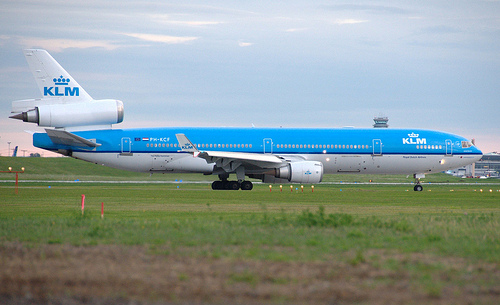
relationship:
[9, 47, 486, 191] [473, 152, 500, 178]
plane at airport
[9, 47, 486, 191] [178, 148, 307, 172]
plane has wing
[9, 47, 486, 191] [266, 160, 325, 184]
plane has engine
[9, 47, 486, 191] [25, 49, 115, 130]
plane has tail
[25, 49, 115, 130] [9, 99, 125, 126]
tail has engine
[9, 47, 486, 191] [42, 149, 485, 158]
plane has stripe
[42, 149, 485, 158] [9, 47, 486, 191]
stripe on plane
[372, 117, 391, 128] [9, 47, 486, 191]
tower behind plane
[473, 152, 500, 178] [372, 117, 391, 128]
airport has tower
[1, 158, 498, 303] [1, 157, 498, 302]
grass in ground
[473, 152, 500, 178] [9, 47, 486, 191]
airport behind plane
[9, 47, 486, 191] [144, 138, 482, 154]
plane has windows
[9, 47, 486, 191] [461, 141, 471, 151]
plane has cockpit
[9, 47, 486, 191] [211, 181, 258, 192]
plane has wheels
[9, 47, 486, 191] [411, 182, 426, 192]
plane has wheels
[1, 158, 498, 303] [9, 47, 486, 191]
grass under plane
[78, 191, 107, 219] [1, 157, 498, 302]
markers in ground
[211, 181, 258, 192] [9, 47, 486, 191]
wheels beneath plane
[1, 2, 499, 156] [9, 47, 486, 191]
sky above plane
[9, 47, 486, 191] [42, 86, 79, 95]
plane has writing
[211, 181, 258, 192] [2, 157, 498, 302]
wheels on ground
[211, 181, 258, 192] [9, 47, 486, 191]
wheels under plane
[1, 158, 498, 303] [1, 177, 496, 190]
grass beside runway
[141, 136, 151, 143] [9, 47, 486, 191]
flag on plane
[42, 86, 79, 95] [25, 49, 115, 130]
writing on tail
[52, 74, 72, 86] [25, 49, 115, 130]
crown on tail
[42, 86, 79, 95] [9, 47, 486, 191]
writing on plane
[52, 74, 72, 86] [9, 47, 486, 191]
crown on plane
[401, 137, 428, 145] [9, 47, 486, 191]
writing on plane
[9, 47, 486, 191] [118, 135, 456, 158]
plane has doors